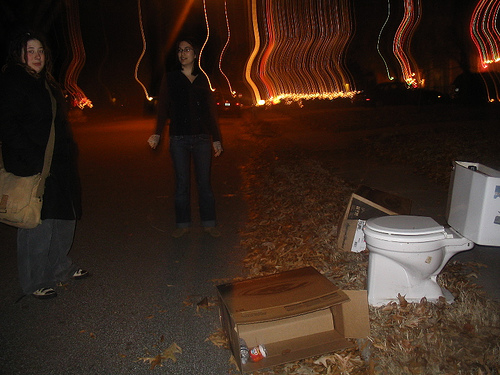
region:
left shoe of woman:
[195, 215, 247, 263]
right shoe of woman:
[160, 214, 190, 249]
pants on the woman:
[160, 128, 235, 214]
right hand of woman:
[138, 125, 178, 167]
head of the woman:
[13, 32, 67, 99]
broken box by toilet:
[190, 258, 380, 360]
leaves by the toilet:
[376, 313, 486, 370]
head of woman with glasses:
[161, 35, 211, 77]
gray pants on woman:
[14, 216, 90, 284]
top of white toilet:
[365, 201, 447, 268]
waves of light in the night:
[238, 8, 497, 119]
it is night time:
[1, 0, 494, 368]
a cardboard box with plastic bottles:
[217, 280, 344, 368]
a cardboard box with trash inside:
[198, 265, 380, 373]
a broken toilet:
[351, 153, 496, 356]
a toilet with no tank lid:
[349, 148, 494, 319]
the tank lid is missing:
[446, 148, 498, 253]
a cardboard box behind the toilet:
[331, 178, 436, 276]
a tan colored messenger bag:
[0, 116, 62, 237]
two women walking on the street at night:
[13, 24, 241, 304]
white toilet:
[364, 159, 499, 306]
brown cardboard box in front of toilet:
[215, 265, 372, 373]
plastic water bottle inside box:
[238, 335, 250, 365]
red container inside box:
[250, 343, 266, 364]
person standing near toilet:
[1, 35, 103, 300]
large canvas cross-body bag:
[2, 76, 58, 226]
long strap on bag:
[33, 78, 59, 203]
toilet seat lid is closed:
[362, 214, 448, 243]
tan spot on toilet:
[425, 255, 432, 262]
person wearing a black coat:
[3, 70, 82, 221]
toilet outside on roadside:
[192, 142, 499, 324]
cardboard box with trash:
[188, 261, 387, 373]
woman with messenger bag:
[3, 34, 83, 252]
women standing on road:
[7, 22, 231, 309]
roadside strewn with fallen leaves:
[238, 122, 465, 370]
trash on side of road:
[209, 129, 499, 374]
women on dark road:
[4, 24, 239, 310]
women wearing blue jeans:
[4, 30, 226, 297]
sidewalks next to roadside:
[256, 103, 497, 312]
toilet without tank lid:
[361, 153, 498, 303]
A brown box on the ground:
[198, 256, 376, 372]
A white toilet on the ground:
[352, 145, 498, 333]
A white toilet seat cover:
[358, 208, 455, 260]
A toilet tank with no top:
[441, 150, 498, 254]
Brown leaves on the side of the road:
[228, 196, 288, 266]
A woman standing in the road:
[138, 30, 239, 243]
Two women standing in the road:
[10, 28, 245, 301]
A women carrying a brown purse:
[1, 27, 98, 274]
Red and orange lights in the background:
[231, 11, 403, 118]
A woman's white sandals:
[14, 241, 106, 312]